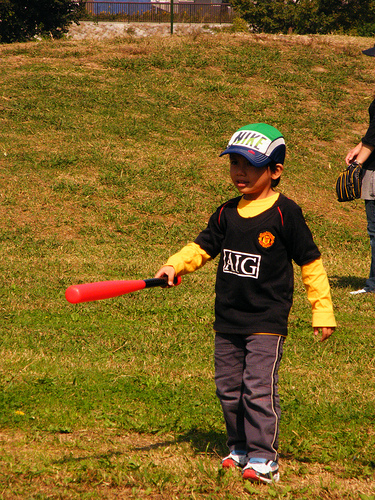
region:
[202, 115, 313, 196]
boy is wearing a hat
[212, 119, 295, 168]
hat is green white blue and black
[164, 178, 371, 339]
boy's shirt is black and yellow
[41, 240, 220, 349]
the bat is red and black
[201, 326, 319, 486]
boy's pants are gray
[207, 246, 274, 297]
white letters on shirt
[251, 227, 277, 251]
gold label on shirt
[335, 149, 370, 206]
person holding a mit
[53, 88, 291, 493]
boy is playing baseball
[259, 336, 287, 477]
black line on pants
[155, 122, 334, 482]
young boy standing outside holding a plastic baseball bat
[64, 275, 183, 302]
small red plastic baseball bat held by a young boy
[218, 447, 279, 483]
tennis shoes with red, white, and blue colors worn by a young boy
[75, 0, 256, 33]
a fence running along the area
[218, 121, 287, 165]
NIKE ball cap worn by a young boy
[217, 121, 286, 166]
green, white, and blue NIKE ballcap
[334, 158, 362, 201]
black and gold baseball glove worn by someone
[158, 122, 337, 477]
small boy dressed in casual clothes playing with a baseball bat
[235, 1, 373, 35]
green and brown shrubbery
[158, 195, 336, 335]
yellow long sleeve shirt worn under a black t-shirt that has white lettering on the front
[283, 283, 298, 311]
part of a shirt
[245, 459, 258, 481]
part of a shoe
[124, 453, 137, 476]
part of a lawn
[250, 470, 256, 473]
tip of a shoe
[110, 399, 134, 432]
part of a field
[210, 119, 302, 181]
green and black nike hat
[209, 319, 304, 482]
grey pants with stripe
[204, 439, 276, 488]
white tennis shoes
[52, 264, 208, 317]
red plastic bat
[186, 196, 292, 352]
black shirt says AIG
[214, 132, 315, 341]
black shirt has red detail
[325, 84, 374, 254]
person behind boy has catchers mitt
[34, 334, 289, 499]
grass has brown patches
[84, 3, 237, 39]
fence at the edge of the grass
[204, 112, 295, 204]
A boy in a green hat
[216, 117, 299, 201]
A boy in a Nike hat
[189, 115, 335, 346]
A boy wearing a black shirt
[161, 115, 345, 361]
A boy wearing a black and yellow shirt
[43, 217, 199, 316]
A boy holding a bat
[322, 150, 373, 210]
Someone wearing a glove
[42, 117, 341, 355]
A boy playing baseball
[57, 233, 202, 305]
Someone holding a red bat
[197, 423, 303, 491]
Two white shoes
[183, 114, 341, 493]
A boy standing on the grass